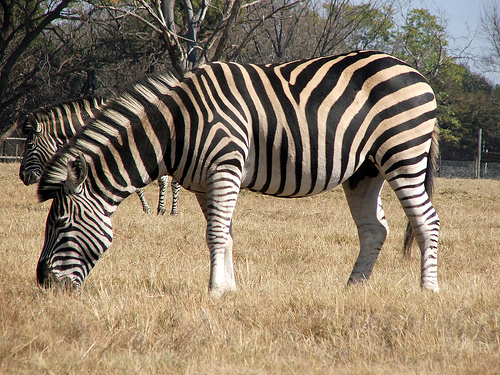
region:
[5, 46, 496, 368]
Animals in a pasture.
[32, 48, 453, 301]
One zebra in a pasture.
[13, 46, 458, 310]
Two zebras grazing in a pasture.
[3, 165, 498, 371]
A pasture of brown grass.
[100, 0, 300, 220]
A tree behind two zebras.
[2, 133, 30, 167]
A fence in the distance.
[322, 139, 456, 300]
Two back legs of a zebra.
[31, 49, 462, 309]
Zebra with his head bent to the ground.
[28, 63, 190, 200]
The mane of a zebra.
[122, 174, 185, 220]
Three legs of a zebra.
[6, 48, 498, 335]
two zebras in enclosed fence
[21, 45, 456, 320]
zebras in pasture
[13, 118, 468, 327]
zebras are black and white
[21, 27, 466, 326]
two zebras eating dried grass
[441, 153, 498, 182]
fence is made of metal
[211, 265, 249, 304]
zebra's hooves are white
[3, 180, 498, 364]
grass is dry and brown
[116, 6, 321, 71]
tree is bare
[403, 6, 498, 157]
trees with green leaves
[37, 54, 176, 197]
zebra's mane is black and white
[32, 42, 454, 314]
A zebra in the foreground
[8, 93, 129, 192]
A zebra is in the background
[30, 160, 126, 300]
Zebra is eating grass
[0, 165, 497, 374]
The grass is tan colored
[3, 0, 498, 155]
Tall trees in the background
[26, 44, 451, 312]
A side view of a zebra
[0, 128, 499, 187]
A fence is in the background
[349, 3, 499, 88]
The sky is clear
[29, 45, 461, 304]
Zebra's stripes are black and white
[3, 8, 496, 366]
Photo was taken outdoors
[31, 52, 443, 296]
Black and white zebra is grazing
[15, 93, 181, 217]
Zebra next to zebra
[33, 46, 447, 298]
Zebra standing in field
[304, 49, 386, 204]
Black stripe on zebra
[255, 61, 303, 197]
Black stripe on zebra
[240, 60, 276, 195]
Black stripe on zebra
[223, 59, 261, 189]
Black stripe on zebra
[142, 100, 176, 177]
Black stripe on zebra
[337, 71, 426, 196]
Black stripe on zebra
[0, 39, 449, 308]
two zebras standing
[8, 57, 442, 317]
two zebras in a field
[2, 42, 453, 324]
two black and white zebras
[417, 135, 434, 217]
black furry tail of zebra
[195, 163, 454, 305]
black and white legs of zebra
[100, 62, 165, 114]
black mane on zebra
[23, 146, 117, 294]
white and black head of zebra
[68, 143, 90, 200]
pointy white and black ear of zebra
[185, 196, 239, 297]
front legs of zebra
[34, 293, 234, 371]
dead grass in large fiedl